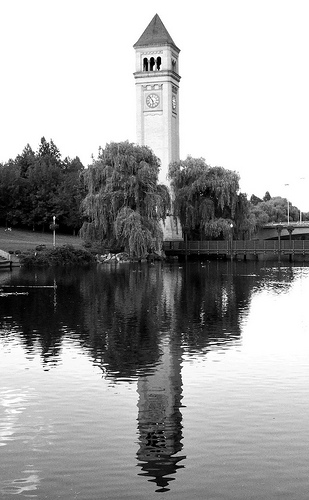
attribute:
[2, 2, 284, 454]
picture — black, white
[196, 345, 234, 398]
water — untroubled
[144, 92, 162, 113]
clock — round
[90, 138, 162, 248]
trees — large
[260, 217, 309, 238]
bridge — small, brown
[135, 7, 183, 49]
roof — pointed, black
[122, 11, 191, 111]
clock bell tower — white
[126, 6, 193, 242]
clock tower — tall, white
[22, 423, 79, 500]
pond — still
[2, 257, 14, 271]
fence — wooden, small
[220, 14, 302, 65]
sky — small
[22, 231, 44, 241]
grass — small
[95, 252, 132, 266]
rocks — gigantic